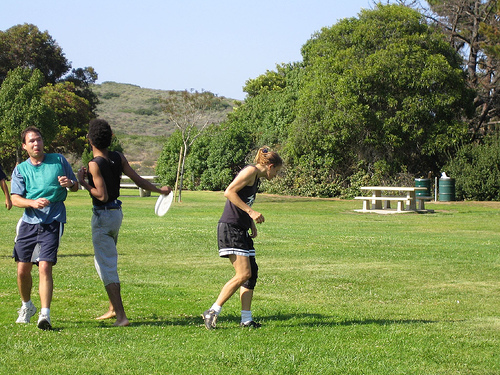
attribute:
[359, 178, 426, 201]
table — Stone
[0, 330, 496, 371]
grass — short,  green and brown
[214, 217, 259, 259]
shorts — black with white stripes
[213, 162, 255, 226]
shirt — black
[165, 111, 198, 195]
tree —  newly planted,  bare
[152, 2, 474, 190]
trees — green, leafy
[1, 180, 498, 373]
grass — short, green, brown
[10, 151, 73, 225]
shirt — blue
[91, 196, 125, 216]
belt — dark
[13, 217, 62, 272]
shorts — blue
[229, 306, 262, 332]
socks —  white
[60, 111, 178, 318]
female —  light skinned ,  barefoot ,  with guy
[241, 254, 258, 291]
brace — black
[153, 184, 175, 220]
white frisbee —   white 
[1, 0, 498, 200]
leaves — green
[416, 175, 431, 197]
metal barrels —  two,  green,   metal ,  for garbage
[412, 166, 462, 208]
garbage cans —  large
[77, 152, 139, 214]
shirt — black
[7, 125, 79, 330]
guy —  backing up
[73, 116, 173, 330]
female —  play fighting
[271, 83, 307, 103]
leaves — green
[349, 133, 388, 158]
branches — brown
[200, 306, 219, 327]
shoes — white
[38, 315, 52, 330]
shoes — white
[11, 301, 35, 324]
shoes — white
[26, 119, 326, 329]
people — three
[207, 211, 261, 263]
shorts — black with two white stripes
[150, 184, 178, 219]
frisbee —  white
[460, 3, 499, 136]
branches — brown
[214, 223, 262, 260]
shorts —  women's,  black,  with white stripes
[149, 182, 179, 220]
frisbee — white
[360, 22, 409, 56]
leaves — green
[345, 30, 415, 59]
branches — brown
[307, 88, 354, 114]
branches — brown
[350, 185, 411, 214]
table —  cement 